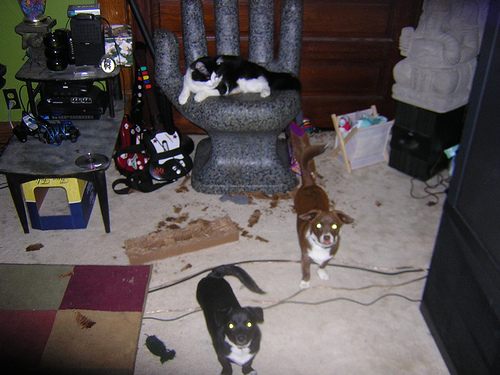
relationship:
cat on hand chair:
[177, 53, 301, 108] [152, 1, 305, 197]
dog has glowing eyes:
[293, 143, 354, 292] [314, 222, 337, 231]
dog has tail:
[293, 143, 354, 292] [297, 141, 329, 186]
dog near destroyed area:
[293, 143, 354, 292] [152, 169, 306, 246]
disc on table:
[74, 152, 111, 171] [1, 63, 131, 234]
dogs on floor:
[197, 143, 354, 374] [1, 99, 456, 373]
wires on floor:
[144, 259, 432, 325] [1, 99, 456, 373]